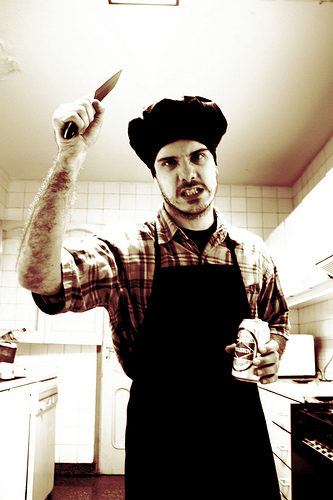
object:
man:
[15, 93, 292, 499]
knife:
[61, 67, 124, 142]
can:
[230, 316, 274, 380]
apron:
[122, 222, 282, 499]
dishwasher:
[26, 373, 58, 499]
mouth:
[179, 184, 206, 201]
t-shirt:
[178, 217, 218, 252]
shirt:
[29, 203, 290, 382]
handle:
[62, 102, 98, 142]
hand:
[225, 340, 281, 386]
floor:
[47, 469, 125, 498]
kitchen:
[0, 0, 332, 499]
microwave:
[276, 332, 316, 377]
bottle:
[0, 327, 27, 345]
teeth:
[184, 188, 201, 197]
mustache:
[173, 182, 209, 192]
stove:
[290, 401, 332, 499]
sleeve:
[32, 219, 120, 317]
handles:
[278, 477, 289, 487]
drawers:
[269, 389, 293, 435]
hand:
[52, 98, 104, 145]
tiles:
[246, 196, 263, 214]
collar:
[155, 206, 231, 252]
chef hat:
[124, 94, 229, 171]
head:
[152, 138, 220, 220]